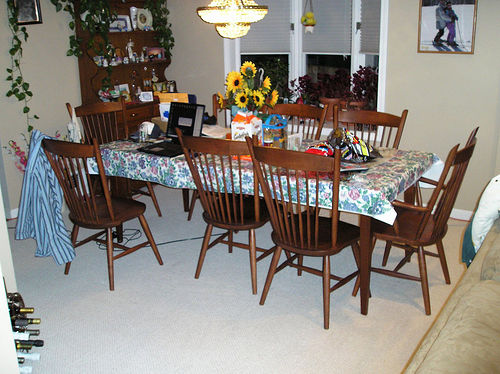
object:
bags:
[305, 127, 383, 171]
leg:
[359, 214, 372, 316]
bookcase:
[74, 1, 173, 199]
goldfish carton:
[231, 110, 266, 163]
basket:
[231, 104, 258, 118]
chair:
[34, 130, 164, 291]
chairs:
[175, 127, 293, 295]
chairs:
[352, 136, 478, 312]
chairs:
[268, 102, 330, 143]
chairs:
[212, 93, 270, 128]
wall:
[374, 0, 499, 218]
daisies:
[216, 60, 281, 111]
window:
[223, 0, 385, 128]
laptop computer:
[135, 102, 205, 158]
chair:
[244, 137, 373, 329]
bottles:
[6, 290, 44, 372]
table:
[74, 138, 437, 316]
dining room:
[0, 0, 500, 374]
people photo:
[415, 0, 477, 56]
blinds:
[235, 1, 381, 56]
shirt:
[14, 129, 77, 265]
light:
[195, 0, 267, 40]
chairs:
[334, 102, 410, 150]